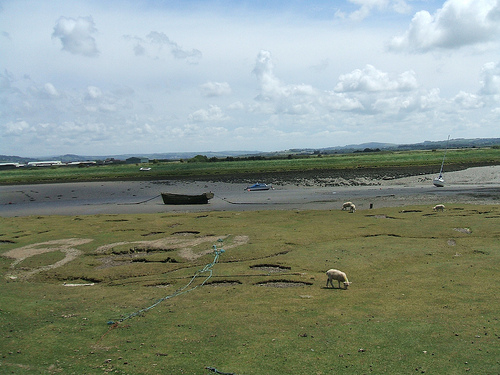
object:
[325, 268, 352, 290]
sheep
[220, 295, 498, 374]
grass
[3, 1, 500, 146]
sky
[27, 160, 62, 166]
buildings